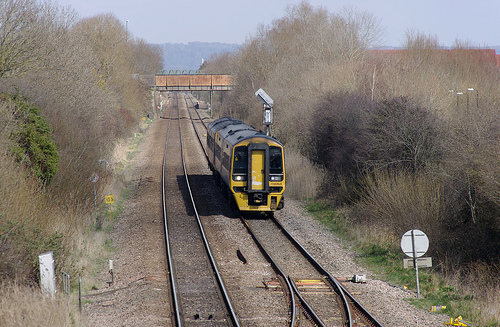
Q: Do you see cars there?
A: No, there are no cars.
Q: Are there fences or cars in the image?
A: No, there are no cars or fences.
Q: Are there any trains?
A: Yes, there is a train.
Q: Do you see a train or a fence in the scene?
A: Yes, there is a train.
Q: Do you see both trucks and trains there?
A: No, there is a train but no trucks.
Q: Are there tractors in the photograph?
A: No, there are no tractors.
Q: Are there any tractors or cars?
A: No, there are no tractors or cars.